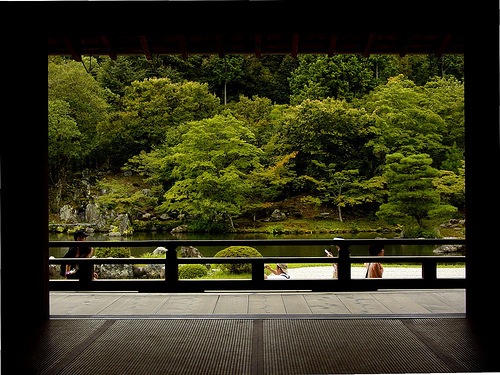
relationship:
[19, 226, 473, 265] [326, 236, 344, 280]
pond behind man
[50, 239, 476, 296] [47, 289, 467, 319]
fence by walkway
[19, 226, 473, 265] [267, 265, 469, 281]
stream by sand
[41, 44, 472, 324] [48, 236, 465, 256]
doorway near lake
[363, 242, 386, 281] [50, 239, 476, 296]
woman beyond fence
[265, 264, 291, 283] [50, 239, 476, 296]
person by fence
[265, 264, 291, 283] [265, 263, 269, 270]
person using a camera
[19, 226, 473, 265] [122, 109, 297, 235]
lake near a tree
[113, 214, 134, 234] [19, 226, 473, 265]
rock near lake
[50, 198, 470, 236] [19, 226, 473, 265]
shore by lake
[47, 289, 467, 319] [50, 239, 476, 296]
walkway near fence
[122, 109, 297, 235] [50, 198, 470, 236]
tree on bank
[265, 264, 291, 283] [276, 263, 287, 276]
person has a head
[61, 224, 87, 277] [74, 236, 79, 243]
person has an ear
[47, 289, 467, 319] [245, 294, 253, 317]
sidewalk has a crack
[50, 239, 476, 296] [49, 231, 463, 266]
fence near pond